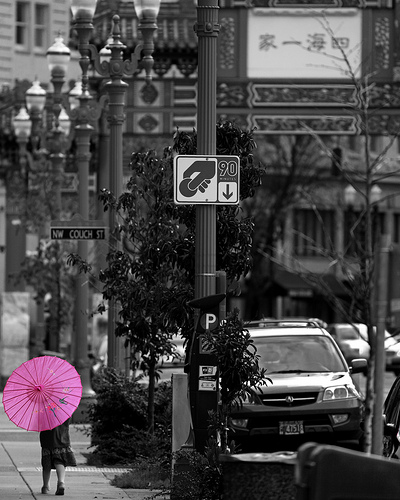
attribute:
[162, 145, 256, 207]
sign — 90 cents, writing, street, several, indicate, japanese, english, pole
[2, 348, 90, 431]
umbrella — purple, color, pink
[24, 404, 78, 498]
girl — little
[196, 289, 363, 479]
suv — parked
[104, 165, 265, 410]
tree — bhind, lying, planted, branch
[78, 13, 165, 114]
lamp — post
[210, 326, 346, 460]
car — acura, parked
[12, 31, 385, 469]
photo — black, white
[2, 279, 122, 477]
lady — under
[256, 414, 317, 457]
plate — license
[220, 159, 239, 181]
number — sign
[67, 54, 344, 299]
background — blurry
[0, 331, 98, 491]
woman — carrying, wearing, walking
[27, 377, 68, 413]
parasol — pink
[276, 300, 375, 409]
vehicle — parked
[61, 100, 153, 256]
pole — light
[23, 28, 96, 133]
light — street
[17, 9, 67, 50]
window — double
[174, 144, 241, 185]
letter — p